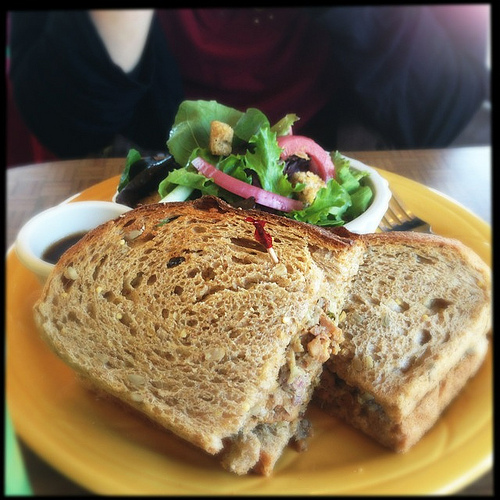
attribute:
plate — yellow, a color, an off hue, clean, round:
[11, 168, 490, 491]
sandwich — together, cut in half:
[34, 201, 489, 479]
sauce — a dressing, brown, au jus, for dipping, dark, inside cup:
[41, 229, 88, 265]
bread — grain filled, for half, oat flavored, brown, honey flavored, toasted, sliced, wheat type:
[314, 227, 490, 454]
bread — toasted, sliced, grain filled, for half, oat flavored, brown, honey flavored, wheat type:
[32, 202, 364, 476]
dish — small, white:
[17, 193, 133, 279]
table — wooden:
[10, 146, 490, 495]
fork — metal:
[376, 190, 434, 233]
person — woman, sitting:
[9, 10, 489, 167]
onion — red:
[189, 156, 307, 216]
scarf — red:
[173, 12, 328, 134]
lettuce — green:
[234, 106, 296, 199]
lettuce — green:
[293, 147, 376, 227]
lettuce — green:
[167, 99, 244, 165]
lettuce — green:
[116, 149, 175, 209]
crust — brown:
[73, 202, 352, 253]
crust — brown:
[360, 232, 485, 279]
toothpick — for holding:
[246, 210, 278, 265]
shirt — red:
[165, 12, 337, 133]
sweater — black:
[11, 12, 488, 159]